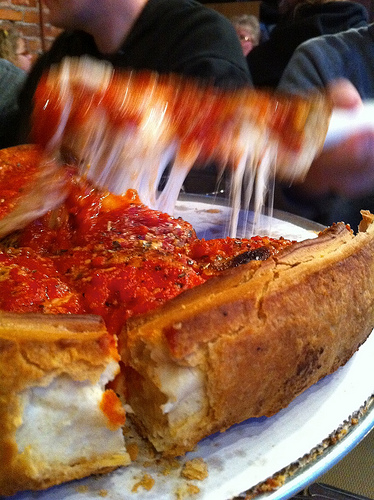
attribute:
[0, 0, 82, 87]
wall — brick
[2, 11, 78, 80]
wall — bricks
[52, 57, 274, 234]
cheese — melted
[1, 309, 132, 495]
crust — thick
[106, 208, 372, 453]
crust — thick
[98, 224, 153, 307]
sauce — Red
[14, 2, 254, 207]
shirt — black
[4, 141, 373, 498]
pizza — deep dish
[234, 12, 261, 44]
lady — grey haired